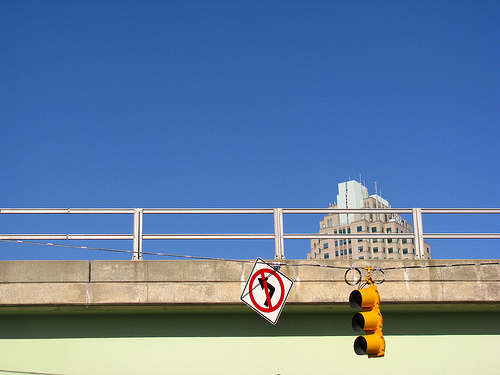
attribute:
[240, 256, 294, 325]
sign — red, black, white, white,red, hanging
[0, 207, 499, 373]
bridge — standing, light brown, concrete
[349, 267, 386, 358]
traffic light — yellow, hanging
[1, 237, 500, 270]
wire — black, long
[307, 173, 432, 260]
building — distant, brown, green, large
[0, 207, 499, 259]
railing — metal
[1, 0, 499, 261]
sky — cloudless, dark blue, deep blue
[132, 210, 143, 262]
post — vertical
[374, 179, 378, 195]
pole — white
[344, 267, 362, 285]
wire — black, circular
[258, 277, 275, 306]
arrow — black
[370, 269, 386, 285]
wire — circular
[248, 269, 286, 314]
circle — red